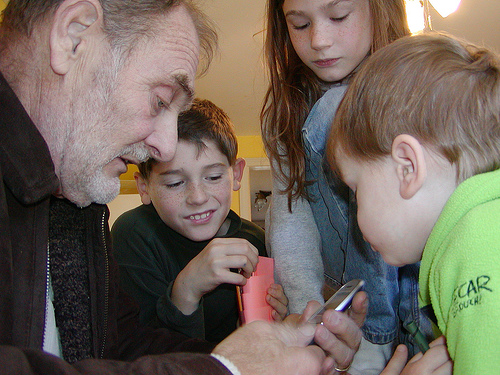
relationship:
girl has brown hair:
[257, 0, 435, 373] [262, 0, 319, 208]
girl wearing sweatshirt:
[257, 0, 435, 373] [266, 105, 325, 319]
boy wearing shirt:
[101, 89, 326, 369] [108, 199, 268, 367]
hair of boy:
[124, 87, 237, 179] [101, 89, 326, 369]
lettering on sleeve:
[448, 272, 493, 315] [430, 200, 499, 374]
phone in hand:
[305, 273, 377, 356] [214, 317, 325, 373]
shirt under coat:
[35, 253, 72, 356] [3, 87, 229, 375]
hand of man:
[214, 303, 324, 373] [0, 1, 370, 373]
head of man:
[2, 0, 217, 207] [0, 1, 370, 373]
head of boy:
[325, 54, 499, 366] [323, 31, 497, 375]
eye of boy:
[203, 174, 222, 183] [108, 89, 267, 353]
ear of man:
[38, 4, 124, 76] [0, 1, 370, 373]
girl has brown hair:
[256, 0, 405, 375] [258, 0, 407, 206]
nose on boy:
[188, 189, 215, 208] [101, 89, 326, 369]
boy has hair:
[320, 29, 499, 372] [324, 23, 499, 264]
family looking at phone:
[0, 0, 498, 373] [291, 276, 364, 348]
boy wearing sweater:
[323, 31, 497, 375] [413, 162, 498, 371]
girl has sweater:
[256, 0, 405, 375] [227, 86, 347, 315]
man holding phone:
[3, 0, 250, 370] [301, 274, 378, 321]